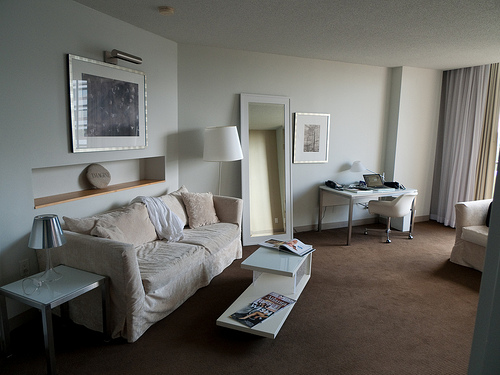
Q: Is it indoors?
A: Yes, it is indoors.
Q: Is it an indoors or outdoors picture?
A: It is indoors.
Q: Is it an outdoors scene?
A: No, it is indoors.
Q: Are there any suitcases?
A: No, there are no suitcases.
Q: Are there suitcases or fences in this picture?
A: No, there are no suitcases or fences.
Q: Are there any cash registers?
A: No, there are no cash registers.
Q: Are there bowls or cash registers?
A: No, there are no cash registers or bowls.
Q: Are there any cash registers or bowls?
A: No, there are no cash registers or bowls.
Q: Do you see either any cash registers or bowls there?
A: No, there are no cash registers or bowls.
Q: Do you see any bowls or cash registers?
A: No, there are no cash registers or bowls.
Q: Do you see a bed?
A: No, there are no beds.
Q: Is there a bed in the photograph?
A: No, there are no beds.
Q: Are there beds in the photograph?
A: No, there are no beds.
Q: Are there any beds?
A: No, there are no beds.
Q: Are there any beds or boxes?
A: No, there are no beds or boxes.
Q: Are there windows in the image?
A: Yes, there is a window.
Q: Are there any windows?
A: Yes, there is a window.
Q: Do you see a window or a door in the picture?
A: Yes, there is a window.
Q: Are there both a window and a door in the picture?
A: No, there is a window but no doors.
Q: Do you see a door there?
A: No, there are no doors.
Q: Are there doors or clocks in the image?
A: No, there are no doors or clocks.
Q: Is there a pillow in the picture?
A: Yes, there is a pillow.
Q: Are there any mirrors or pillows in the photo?
A: Yes, there is a pillow.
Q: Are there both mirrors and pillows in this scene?
A: Yes, there are both a pillow and a mirror.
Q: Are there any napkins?
A: No, there are no napkins.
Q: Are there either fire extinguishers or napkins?
A: No, there are no napkins or fire extinguishers.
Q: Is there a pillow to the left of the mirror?
A: Yes, there is a pillow to the left of the mirror.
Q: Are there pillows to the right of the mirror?
A: No, the pillow is to the left of the mirror.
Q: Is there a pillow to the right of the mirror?
A: No, the pillow is to the left of the mirror.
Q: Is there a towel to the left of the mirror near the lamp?
A: No, there is a pillow to the left of the mirror.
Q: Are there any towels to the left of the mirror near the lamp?
A: No, there is a pillow to the left of the mirror.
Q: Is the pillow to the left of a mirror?
A: Yes, the pillow is to the left of a mirror.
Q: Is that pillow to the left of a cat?
A: No, the pillow is to the left of a mirror.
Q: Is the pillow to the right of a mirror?
A: No, the pillow is to the left of a mirror.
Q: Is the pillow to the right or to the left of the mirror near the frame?
A: The pillow is to the left of the mirror.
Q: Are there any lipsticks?
A: No, there are no lipsticks.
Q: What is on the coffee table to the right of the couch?
A: The magazine is on the coffee table.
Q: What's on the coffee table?
A: The magazine is on the coffee table.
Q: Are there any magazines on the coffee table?
A: Yes, there is a magazine on the coffee table.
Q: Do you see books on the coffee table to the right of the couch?
A: No, there is a magazine on the coffee table.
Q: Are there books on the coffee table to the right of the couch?
A: No, there is a magazine on the coffee table.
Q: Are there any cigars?
A: No, there are no cigars.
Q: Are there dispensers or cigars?
A: No, there are no cigars or dispensers.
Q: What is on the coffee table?
A: The magazine is on the coffee table.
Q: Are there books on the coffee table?
A: No, there is a magazine on the coffee table.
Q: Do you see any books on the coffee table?
A: No, there is a magazine on the coffee table.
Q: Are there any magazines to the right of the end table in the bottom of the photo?
A: Yes, there is a magazine to the right of the end table.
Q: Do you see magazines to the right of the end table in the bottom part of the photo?
A: Yes, there is a magazine to the right of the end table.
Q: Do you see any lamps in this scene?
A: Yes, there is a lamp.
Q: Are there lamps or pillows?
A: Yes, there is a lamp.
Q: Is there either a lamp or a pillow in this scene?
A: Yes, there is a lamp.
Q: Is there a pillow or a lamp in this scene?
A: Yes, there is a lamp.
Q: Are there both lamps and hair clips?
A: No, there is a lamp but no hair clips.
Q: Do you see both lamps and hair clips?
A: No, there is a lamp but no hair clips.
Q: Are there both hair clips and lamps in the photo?
A: No, there is a lamp but no hair clips.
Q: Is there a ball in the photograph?
A: No, there are no balls.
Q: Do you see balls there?
A: No, there are no balls.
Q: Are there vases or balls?
A: No, there are no balls or vases.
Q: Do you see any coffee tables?
A: Yes, there is a coffee table.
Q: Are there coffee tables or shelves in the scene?
A: Yes, there is a coffee table.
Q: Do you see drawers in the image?
A: No, there are no drawers.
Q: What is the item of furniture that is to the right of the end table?
A: The piece of furniture is a coffee table.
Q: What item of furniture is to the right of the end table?
A: The piece of furniture is a coffee table.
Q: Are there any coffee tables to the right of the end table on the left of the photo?
A: Yes, there is a coffee table to the right of the end table.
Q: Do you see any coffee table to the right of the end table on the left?
A: Yes, there is a coffee table to the right of the end table.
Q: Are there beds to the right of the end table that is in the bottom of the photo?
A: No, there is a coffee table to the right of the end table.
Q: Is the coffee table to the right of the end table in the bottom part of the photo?
A: Yes, the coffee table is to the right of the end table.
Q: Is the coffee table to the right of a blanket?
A: No, the coffee table is to the right of the end table.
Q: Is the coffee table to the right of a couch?
A: Yes, the coffee table is to the right of a couch.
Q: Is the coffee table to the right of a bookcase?
A: No, the coffee table is to the right of a couch.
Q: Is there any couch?
A: Yes, there is a couch.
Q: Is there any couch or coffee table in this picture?
A: Yes, there is a couch.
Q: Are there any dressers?
A: No, there are no dressers.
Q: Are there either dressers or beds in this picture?
A: No, there are no dressers or beds.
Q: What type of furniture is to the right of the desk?
A: The piece of furniture is a couch.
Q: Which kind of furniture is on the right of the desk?
A: The piece of furniture is a couch.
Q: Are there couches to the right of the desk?
A: Yes, there is a couch to the right of the desk.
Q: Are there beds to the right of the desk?
A: No, there is a couch to the right of the desk.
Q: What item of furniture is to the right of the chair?
A: The piece of furniture is a couch.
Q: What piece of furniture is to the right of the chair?
A: The piece of furniture is a couch.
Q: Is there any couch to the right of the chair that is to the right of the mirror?
A: Yes, there is a couch to the right of the chair.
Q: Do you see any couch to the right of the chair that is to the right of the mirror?
A: Yes, there is a couch to the right of the chair.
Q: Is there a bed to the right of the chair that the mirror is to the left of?
A: No, there is a couch to the right of the chair.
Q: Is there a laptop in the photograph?
A: Yes, there is a laptop.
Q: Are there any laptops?
A: Yes, there is a laptop.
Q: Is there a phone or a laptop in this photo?
A: Yes, there is a laptop.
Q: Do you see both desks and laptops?
A: Yes, there are both a laptop and a desk.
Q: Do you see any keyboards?
A: No, there are no keyboards.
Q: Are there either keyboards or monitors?
A: No, there are no keyboards or monitors.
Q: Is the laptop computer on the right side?
A: Yes, the laptop computer is on the right of the image.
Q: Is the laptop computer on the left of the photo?
A: No, the laptop computer is on the right of the image.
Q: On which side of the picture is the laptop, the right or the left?
A: The laptop is on the right of the image.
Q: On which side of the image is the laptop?
A: The laptop is on the right of the image.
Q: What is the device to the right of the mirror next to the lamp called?
A: The device is a laptop.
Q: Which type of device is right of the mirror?
A: The device is a laptop.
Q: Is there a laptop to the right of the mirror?
A: Yes, there is a laptop to the right of the mirror.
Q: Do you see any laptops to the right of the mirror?
A: Yes, there is a laptop to the right of the mirror.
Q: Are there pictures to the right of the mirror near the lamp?
A: No, there is a laptop to the right of the mirror.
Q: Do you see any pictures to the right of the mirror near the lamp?
A: No, there is a laptop to the right of the mirror.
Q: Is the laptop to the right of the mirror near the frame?
A: Yes, the laptop is to the right of the mirror.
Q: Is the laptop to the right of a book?
A: No, the laptop is to the right of the mirror.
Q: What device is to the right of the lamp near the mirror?
A: The device is a laptop.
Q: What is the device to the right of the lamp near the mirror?
A: The device is a laptop.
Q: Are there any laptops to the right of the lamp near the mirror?
A: Yes, there is a laptop to the right of the lamp.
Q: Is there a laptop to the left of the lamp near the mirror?
A: No, the laptop is to the right of the lamp.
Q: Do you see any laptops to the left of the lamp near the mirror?
A: No, the laptop is to the right of the lamp.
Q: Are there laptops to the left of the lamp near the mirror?
A: No, the laptop is to the right of the lamp.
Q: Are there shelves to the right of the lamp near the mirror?
A: No, there is a laptop to the right of the lamp.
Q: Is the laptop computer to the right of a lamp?
A: Yes, the laptop computer is to the right of a lamp.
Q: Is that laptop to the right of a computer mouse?
A: No, the laptop is to the right of a lamp.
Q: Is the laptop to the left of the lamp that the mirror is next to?
A: No, the laptop is to the right of the lamp.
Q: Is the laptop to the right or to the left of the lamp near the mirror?
A: The laptop is to the right of the lamp.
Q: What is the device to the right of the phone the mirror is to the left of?
A: The device is a laptop.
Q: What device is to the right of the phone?
A: The device is a laptop.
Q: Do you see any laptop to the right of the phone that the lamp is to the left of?
A: Yes, there is a laptop to the right of the telephone.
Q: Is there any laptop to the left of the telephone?
A: No, the laptop is to the right of the telephone.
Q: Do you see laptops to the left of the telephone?
A: No, the laptop is to the right of the telephone.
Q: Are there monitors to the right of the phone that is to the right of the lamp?
A: No, there is a laptop to the right of the telephone.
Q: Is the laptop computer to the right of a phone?
A: Yes, the laptop computer is to the right of a phone.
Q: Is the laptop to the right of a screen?
A: No, the laptop is to the right of a phone.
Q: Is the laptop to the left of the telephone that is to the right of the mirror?
A: No, the laptop is to the right of the telephone.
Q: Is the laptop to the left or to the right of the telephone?
A: The laptop is to the right of the telephone.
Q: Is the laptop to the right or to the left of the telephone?
A: The laptop is to the right of the telephone.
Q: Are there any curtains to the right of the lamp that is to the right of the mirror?
A: No, there is a laptop to the right of the lamp.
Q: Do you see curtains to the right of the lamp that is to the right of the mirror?
A: No, there is a laptop to the right of the lamp.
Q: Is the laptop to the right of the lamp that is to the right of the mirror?
A: Yes, the laptop is to the right of the lamp.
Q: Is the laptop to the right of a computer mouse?
A: No, the laptop is to the right of the lamp.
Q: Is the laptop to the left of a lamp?
A: No, the laptop is to the right of a lamp.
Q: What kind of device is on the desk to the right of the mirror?
A: The device is a laptop.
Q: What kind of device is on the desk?
A: The device is a laptop.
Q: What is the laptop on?
A: The laptop is on the desk.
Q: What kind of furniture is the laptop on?
A: The laptop is on the desk.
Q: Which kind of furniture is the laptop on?
A: The laptop is on the desk.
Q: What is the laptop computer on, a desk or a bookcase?
A: The laptop computer is on a desk.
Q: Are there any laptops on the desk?
A: Yes, there is a laptop on the desk.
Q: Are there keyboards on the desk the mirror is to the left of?
A: No, there is a laptop on the desk.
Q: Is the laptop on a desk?
A: Yes, the laptop is on a desk.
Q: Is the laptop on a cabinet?
A: No, the laptop is on a desk.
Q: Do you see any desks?
A: Yes, there is a desk.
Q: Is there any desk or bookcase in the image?
A: Yes, there is a desk.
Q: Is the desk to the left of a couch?
A: No, the desk is to the right of a couch.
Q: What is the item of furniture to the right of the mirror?
A: The piece of furniture is a desk.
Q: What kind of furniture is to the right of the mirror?
A: The piece of furniture is a desk.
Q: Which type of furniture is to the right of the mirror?
A: The piece of furniture is a desk.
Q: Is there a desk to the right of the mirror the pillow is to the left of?
A: Yes, there is a desk to the right of the mirror.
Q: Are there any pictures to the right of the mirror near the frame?
A: No, there is a desk to the right of the mirror.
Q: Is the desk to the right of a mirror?
A: Yes, the desk is to the right of a mirror.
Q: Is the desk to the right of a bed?
A: No, the desk is to the right of a mirror.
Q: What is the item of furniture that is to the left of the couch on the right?
A: The piece of furniture is a desk.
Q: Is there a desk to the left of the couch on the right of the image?
A: Yes, there is a desk to the left of the couch.